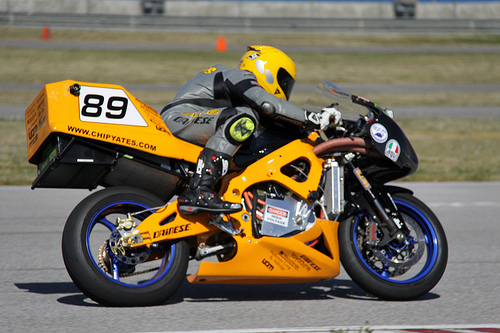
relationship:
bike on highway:
[24, 75, 449, 311] [0, 175, 499, 330]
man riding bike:
[153, 40, 344, 221] [24, 75, 449, 311]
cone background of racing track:
[213, 33, 230, 52] [0, 183, 500, 331]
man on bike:
[159, 44, 344, 218] [20, 71, 450, 311]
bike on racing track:
[20, 71, 450, 311] [0, 183, 500, 331]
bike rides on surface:
[20, 71, 450, 311] [6, 183, 498, 330]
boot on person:
[176, 143, 246, 219] [18, 76, 449, 305]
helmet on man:
[235, 35, 302, 106] [159, 44, 344, 218]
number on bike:
[79, 92, 131, 121] [20, 71, 450, 311]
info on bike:
[65, 120, 162, 157] [20, 71, 450, 311]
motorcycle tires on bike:
[56, 183, 190, 304] [20, 71, 450, 311]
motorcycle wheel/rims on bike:
[338, 186, 452, 300] [20, 71, 450, 311]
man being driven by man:
[159, 44, 344, 218] [162, 43, 346, 214]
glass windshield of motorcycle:
[316, 82, 364, 121] [13, 68, 451, 331]